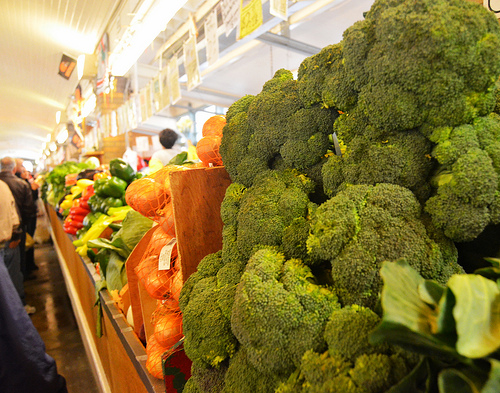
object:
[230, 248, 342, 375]
broccoli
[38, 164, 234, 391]
stand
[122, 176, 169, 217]
onion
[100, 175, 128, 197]
pepper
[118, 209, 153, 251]
lettuce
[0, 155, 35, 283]
man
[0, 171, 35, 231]
jacket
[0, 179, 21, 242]
coat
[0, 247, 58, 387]
jeans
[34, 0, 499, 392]
produce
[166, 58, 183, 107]
sign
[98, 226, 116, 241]
carrot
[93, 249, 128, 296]
cabbage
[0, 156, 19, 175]
head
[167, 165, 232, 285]
wood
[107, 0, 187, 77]
light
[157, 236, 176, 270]
label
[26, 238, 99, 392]
floor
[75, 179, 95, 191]
zucchini